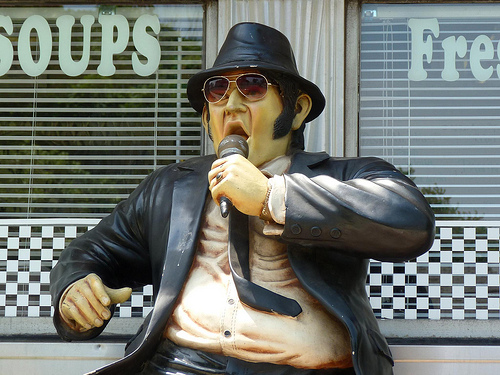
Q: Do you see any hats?
A: Yes, there is a hat.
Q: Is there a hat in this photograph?
A: Yes, there is a hat.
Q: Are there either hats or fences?
A: Yes, there is a hat.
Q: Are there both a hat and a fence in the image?
A: No, there is a hat but no fences.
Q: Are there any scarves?
A: No, there are no scarves.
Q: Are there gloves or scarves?
A: No, there are no scarves or gloves.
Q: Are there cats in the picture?
A: No, there are no cats.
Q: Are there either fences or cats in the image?
A: No, there are no cats or fences.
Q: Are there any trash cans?
A: No, there are no trash cans.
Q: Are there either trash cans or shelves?
A: No, there are no trash cans or shelves.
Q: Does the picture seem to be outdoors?
A: Yes, the picture is outdoors.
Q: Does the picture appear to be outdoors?
A: Yes, the picture is outdoors.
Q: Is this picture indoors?
A: No, the picture is outdoors.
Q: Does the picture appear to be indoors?
A: No, the picture is outdoors.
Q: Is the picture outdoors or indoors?
A: The picture is outdoors.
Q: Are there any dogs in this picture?
A: No, there are no dogs.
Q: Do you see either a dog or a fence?
A: No, there are no dogs or fences.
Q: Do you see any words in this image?
A: Yes, there are words.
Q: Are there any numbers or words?
A: Yes, there are words.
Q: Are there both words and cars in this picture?
A: No, there are words but no cars.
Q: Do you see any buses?
A: No, there are no buses.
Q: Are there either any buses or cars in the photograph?
A: No, there are no buses or cars.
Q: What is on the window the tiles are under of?
A: The words are on the window.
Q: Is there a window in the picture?
A: Yes, there is a window.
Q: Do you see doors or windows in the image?
A: Yes, there is a window.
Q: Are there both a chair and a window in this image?
A: No, there is a window but no chairs.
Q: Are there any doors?
A: No, there are no doors.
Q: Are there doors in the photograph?
A: No, there are no doors.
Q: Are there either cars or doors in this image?
A: No, there are no doors or cars.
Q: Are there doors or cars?
A: No, there are no doors or cars.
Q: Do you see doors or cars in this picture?
A: No, there are no doors or cars.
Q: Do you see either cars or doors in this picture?
A: No, there are no doors or cars.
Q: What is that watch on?
A: The watch is on the statue.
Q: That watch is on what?
A: The watch is on the statue.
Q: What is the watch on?
A: The watch is on the statue.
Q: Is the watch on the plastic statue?
A: Yes, the watch is on the statue.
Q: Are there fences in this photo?
A: No, there are no fences.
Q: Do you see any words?
A: Yes, there are words.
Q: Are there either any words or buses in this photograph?
A: Yes, there are words.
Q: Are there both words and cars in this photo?
A: No, there are words but no cars.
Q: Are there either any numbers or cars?
A: No, there are no cars or numbers.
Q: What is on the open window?
A: The words are on the window.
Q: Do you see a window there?
A: Yes, there is a window.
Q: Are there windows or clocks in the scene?
A: Yes, there is a window.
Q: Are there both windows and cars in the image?
A: No, there is a window but no cars.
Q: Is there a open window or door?
A: Yes, there is an open window.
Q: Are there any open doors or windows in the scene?
A: Yes, there is an open window.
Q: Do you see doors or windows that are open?
A: Yes, the window is open.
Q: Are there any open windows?
A: Yes, there is an open window.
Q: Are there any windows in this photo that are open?
A: Yes, there is a window that is open.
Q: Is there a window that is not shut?
A: Yes, there is a open window.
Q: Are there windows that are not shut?
A: Yes, there is a open window.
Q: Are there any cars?
A: No, there are no cars.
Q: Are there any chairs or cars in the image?
A: No, there are no cars or chairs.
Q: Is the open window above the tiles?
A: Yes, the window is above the tiles.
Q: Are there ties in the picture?
A: Yes, there is a tie.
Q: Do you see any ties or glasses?
A: Yes, there is a tie.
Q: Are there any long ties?
A: Yes, there is a long tie.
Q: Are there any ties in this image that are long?
A: Yes, there is a tie that is long.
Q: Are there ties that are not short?
A: Yes, there is a long tie.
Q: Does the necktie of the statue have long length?
A: Yes, the tie is long.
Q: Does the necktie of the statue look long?
A: Yes, the tie is long.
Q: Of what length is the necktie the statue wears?
A: The necktie is long.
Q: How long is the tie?
A: The tie is long.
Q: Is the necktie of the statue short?
A: No, the necktie is long.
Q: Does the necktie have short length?
A: No, the necktie is long.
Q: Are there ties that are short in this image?
A: No, there is a tie but it is long.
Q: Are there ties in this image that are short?
A: No, there is a tie but it is long.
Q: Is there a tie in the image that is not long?
A: No, there is a tie but it is long.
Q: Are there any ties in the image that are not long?
A: No, there is a tie but it is long.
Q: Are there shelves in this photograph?
A: No, there are no shelves.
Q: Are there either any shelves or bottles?
A: No, there are no shelves or bottles.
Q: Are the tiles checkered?
A: Yes, the tiles are checkered.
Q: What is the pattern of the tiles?
A: The tiles are checkered.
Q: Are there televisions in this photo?
A: No, there are no televisions.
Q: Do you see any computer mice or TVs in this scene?
A: No, there are no TVs or computer mice.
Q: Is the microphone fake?
A: Yes, the microphone is fake.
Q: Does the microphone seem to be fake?
A: Yes, the microphone is fake.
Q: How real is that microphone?
A: The microphone is fake.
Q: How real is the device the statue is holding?
A: The microphone is fake.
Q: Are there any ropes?
A: No, there are no ropes.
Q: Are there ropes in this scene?
A: No, there are no ropes.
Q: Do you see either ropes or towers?
A: No, there are no ropes or towers.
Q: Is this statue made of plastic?
A: Yes, the statue is made of plastic.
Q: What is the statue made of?
A: The statue is made of plastic.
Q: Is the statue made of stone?
A: No, the statue is made of plastic.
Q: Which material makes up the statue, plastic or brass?
A: The statue is made of plastic.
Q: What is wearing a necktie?
A: The statue is wearing a necktie.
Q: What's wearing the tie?
A: The statue is wearing a necktie.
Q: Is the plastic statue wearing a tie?
A: Yes, the statue is wearing a tie.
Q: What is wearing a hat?
A: The statue is wearing a hat.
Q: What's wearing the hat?
A: The statue is wearing a hat.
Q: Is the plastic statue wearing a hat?
A: Yes, the statue is wearing a hat.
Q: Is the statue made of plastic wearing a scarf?
A: No, the statue is wearing a hat.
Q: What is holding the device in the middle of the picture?
A: The statue is holding the microphone.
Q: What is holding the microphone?
A: The statue is holding the microphone.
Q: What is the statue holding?
A: The statue is holding the microphone.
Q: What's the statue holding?
A: The statue is holding the microphone.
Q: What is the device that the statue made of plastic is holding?
A: The device is a microphone.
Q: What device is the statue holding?
A: The statue is holding the microphone.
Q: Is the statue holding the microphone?
A: Yes, the statue is holding the microphone.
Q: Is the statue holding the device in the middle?
A: Yes, the statue is holding the microphone.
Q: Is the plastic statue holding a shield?
A: No, the statue is holding the microphone.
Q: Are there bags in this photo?
A: No, there are no bags.